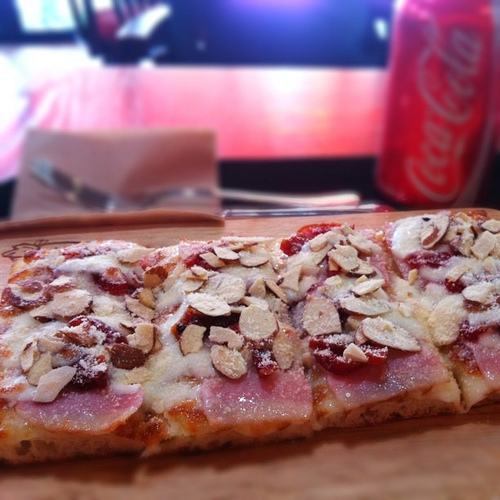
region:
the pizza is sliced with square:
[145, 224, 429, 469]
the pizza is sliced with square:
[112, 201, 326, 349]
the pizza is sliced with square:
[150, 224, 308, 314]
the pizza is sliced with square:
[199, 237, 309, 374]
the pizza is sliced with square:
[205, 244, 347, 466]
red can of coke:
[354, 3, 478, 173]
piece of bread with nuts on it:
[150, 211, 295, 456]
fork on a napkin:
[25, 113, 347, 233]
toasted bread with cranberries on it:
[164, 356, 315, 458]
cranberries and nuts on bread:
[277, 217, 357, 271]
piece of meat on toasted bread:
[312, 334, 437, 443]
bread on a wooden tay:
[27, 229, 463, 496]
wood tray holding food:
[122, 225, 164, 242]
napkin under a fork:
[19, 150, 429, 217]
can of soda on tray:
[372, 3, 472, 222]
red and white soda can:
[372, 5, 496, 210]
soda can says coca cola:
[357, 1, 497, 188]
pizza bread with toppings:
[44, 230, 489, 455]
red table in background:
[64, 67, 381, 174]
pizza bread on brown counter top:
[18, 214, 498, 479]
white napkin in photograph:
[28, 138, 283, 249]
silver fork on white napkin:
[18, 121, 425, 225]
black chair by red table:
[90, 14, 404, 94]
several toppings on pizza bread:
[50, 262, 404, 394]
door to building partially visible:
[17, 4, 122, 55]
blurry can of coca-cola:
[387, 2, 491, 209]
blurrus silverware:
[12, 155, 390, 222]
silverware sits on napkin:
[8, 119, 380, 224]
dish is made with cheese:
[2, 227, 492, 452]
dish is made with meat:
[1, 208, 488, 460]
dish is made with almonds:
[5, 231, 485, 453]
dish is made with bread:
[11, 230, 487, 456]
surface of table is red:
[5, 60, 398, 181]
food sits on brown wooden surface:
[0, 207, 491, 493]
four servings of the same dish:
[8, 203, 494, 469]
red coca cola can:
[365, 0, 499, 210]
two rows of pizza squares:
[3, 213, 496, 464]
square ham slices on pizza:
[188, 368, 457, 448]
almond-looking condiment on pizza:
[153, 243, 301, 380]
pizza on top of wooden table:
[4, 213, 491, 497]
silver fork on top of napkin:
[3, 134, 368, 224]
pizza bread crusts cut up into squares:
[5, 383, 486, 468]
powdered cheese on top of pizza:
[19, 247, 205, 405]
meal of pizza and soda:
[3, 31, 493, 480]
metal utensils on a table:
[6, 153, 380, 222]